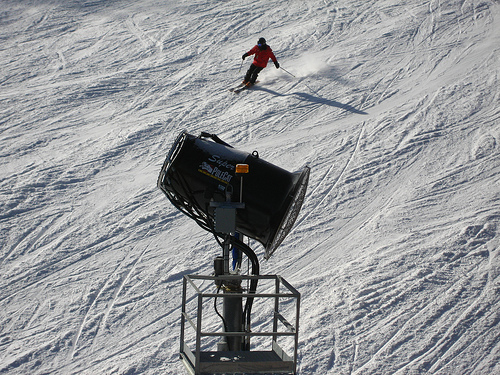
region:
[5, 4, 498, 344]
The ground is snow covered.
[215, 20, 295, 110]
He is skiing.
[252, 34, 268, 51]
His helmet is black.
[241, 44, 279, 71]
His jacket is red.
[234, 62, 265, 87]
His pants are black.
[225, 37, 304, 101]
He has two poles.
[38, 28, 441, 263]
He is skiing down the mountain.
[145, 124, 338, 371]
The light is black.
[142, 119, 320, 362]
The light is off.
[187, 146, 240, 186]
the lettering is white.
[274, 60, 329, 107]
This is a skiing pole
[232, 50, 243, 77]
This is a skiing pole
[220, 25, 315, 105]
a person is skiing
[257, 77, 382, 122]
shadow of a person skiing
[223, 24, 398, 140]
a person in red skiing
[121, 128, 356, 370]
A public alarm system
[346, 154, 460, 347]
This is a heap of ice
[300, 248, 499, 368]
This is a heap of ice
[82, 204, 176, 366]
This is a heap of ice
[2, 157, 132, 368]
This is a heap of ice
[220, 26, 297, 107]
the skier going down the mountain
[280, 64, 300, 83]
the black pole in the snow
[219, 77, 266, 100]
the skies on the persons feet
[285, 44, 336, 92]
the skier kicking up snow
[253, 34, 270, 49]
the mask on the skiers face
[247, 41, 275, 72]
the red jacket of the skier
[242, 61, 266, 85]
the black pants of the skier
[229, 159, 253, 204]
the orange light the pole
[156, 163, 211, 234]
wires going into the light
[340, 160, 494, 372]
ski lines on the snowy mountain slope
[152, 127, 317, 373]
Huge floodlight on a mast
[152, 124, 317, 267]
Dark colored head of a floodlight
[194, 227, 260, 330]
Thick cabling to the mast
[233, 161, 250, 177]
Square brown colored lighting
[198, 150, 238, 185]
Branding on a dark surface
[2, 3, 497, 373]
Snow surface with many track imprints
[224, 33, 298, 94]
Person skiing on the snow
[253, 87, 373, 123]
Long shadow of the snow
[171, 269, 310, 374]
Square shaped metal frame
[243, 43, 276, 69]
Red colored thick jacket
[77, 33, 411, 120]
a person snowbaording in the mountain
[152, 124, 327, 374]
light with steel stand in the snow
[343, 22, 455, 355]
a mountain full of snow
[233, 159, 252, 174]
small yellow color light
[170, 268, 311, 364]
steel stand of the light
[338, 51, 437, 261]
white color snow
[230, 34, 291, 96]
a person holding ski poles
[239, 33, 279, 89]
a person wearing snowsuit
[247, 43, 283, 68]
person wearing red color jacket with black color gloves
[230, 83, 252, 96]
snowboard in the snow